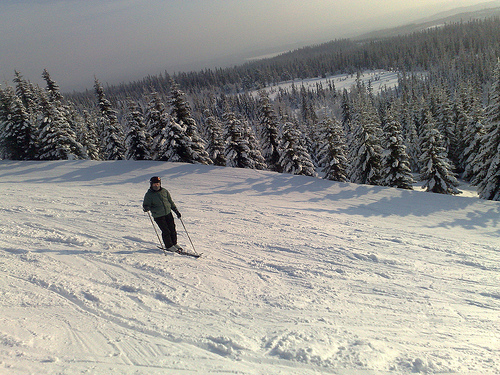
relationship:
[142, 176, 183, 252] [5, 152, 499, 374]
athlete on slope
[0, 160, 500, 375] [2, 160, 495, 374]
field in snow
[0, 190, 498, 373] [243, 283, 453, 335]
tracks in snow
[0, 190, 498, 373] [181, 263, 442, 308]
tracks in snow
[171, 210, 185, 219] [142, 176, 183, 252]
hand of athlete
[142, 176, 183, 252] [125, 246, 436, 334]
athlete on slope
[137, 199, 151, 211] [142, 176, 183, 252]
hand of athlete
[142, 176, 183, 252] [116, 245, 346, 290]
athlete on slope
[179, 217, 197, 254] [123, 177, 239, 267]
poles of athlete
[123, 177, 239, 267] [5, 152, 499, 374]
athlete on slope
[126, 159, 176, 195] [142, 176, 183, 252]
head of athlete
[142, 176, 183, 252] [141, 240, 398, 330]
athlete on slope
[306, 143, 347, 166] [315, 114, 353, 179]
snow covered tree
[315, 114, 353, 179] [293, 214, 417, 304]
tree on slope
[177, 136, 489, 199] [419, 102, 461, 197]
snow on tree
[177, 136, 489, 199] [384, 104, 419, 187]
snow on tree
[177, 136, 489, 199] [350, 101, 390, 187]
snow on tree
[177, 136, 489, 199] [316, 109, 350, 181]
snow on tree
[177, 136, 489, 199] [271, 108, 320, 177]
snow on tree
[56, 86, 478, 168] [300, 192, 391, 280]
trees covered in snow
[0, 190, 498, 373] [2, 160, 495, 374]
tracks in snow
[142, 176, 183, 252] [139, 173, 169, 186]
athlete wearing helmet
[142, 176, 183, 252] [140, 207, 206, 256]
athlete holding poles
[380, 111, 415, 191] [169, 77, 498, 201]
tree covered with snow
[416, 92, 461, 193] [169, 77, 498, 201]
tree covered with snow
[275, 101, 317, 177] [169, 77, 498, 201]
tree covered with snow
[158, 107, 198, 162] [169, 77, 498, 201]
tree covered with snow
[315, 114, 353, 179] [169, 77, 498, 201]
tree covered with snow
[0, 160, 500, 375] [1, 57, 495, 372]
field covered in snow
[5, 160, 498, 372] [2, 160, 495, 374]
field covered with snow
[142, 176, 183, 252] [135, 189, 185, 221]
athlete wearing a coat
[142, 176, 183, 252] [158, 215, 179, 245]
athlete wearing pants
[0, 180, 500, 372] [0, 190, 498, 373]
slope has tracks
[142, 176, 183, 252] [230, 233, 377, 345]
athlete skiing in snow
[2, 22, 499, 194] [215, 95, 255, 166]
snow covers tree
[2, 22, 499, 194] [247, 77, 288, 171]
snow covers tree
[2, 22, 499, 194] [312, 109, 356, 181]
snow covers tree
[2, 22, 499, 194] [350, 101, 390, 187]
snow covers tree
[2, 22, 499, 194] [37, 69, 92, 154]
snow covers tree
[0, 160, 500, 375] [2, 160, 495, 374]
field are in snow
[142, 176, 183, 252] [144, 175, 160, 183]
athlete wears helmet